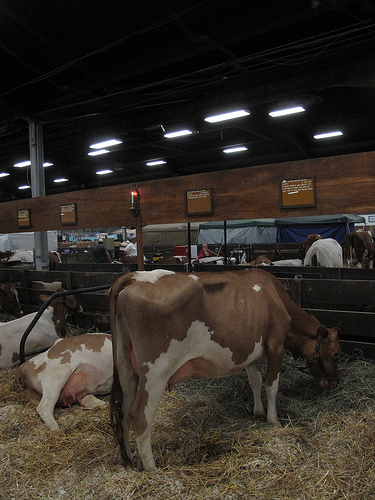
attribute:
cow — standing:
[295, 230, 350, 272]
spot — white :
[139, 268, 199, 287]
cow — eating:
[106, 259, 340, 462]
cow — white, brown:
[15, 327, 116, 421]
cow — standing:
[112, 264, 344, 476]